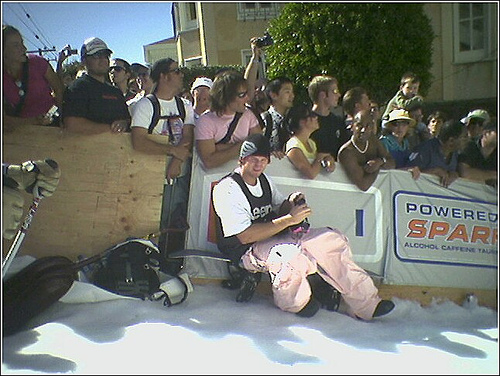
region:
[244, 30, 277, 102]
Arm holding a camera raised high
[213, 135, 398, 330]
Man sitting down wearing pink pants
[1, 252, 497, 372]
The ground is covered in white snow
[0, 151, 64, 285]
Gloved hand holding a ski pole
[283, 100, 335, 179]
Woman is wearing a yellow top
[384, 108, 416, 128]
A white hat with medium brim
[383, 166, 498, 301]
A white, blue and orange advertisement on wall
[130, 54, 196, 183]
Man in white t-shirt wearing a backpack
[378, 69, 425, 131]
Small boy sitting on man's shoulders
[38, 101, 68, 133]
Silver camera held over wall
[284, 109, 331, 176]
woman wearing a yellow shirt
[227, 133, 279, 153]
black and gray hat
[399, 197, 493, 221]
powered on the sign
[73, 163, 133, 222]
brown board in front of people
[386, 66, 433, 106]
kid with green shirt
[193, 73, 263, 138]
man with black strap across his shoulder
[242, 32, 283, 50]
person holding camera in the air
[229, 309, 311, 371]
shadows of people on the ground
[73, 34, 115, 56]
blue and white cap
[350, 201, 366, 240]
blue stripe on the banner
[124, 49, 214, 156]
a man wearing a white shirt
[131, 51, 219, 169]
a man wearing his hat backwards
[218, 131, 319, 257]
a man wearing a black hat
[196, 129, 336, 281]
a man wearing a black vest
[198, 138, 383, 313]
a man wearing ski pants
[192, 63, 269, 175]
a man wearing a pink shirt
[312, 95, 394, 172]
a man wearing no shirt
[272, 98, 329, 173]
a woman wearing a yellow shirt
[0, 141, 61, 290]
a person holding ski poles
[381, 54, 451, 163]
a man holding a child on his shoulders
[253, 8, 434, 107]
part of a large green tree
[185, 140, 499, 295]
a long white sign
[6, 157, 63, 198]
a brown glove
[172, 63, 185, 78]
dark black sunglasses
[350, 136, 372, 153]
a man's white necklace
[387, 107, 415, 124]
a woman's brown hat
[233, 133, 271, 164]
a black and white baseball cap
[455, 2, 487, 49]
part of a window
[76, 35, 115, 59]
a white baseball cap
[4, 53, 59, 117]
part of a woman's pink shirt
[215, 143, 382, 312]
man wearing black tank top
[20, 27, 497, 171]
people standing behind blockade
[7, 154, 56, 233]
hands holding ski poles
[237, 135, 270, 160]
black and gray knit cap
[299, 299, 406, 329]
black shoes of man wearing black tank top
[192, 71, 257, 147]
man wearing pink shirt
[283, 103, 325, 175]
woman wearing yellow shirt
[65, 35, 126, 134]
man wearing black and white ball cap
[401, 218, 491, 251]
orange lettering on white background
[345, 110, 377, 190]
man wearing white necklace